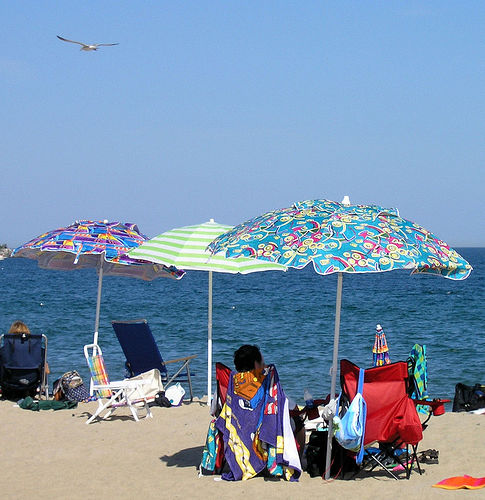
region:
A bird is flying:
[49, 27, 125, 62]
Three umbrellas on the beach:
[9, 190, 476, 478]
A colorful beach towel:
[197, 360, 306, 481]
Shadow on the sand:
[158, 441, 209, 471]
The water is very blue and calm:
[2, 245, 482, 411]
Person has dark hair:
[230, 340, 267, 375]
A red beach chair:
[335, 353, 427, 481]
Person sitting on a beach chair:
[3, 318, 52, 402]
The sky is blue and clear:
[1, 4, 483, 247]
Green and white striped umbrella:
[122, 214, 292, 280]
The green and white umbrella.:
[134, 218, 287, 276]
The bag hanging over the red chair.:
[336, 361, 363, 446]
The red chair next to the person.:
[338, 354, 419, 476]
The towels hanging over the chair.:
[221, 370, 293, 480]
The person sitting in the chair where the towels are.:
[233, 341, 307, 453]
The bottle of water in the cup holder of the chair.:
[301, 386, 313, 405]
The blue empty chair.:
[114, 320, 193, 397]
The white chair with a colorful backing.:
[84, 341, 149, 419]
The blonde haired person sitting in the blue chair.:
[9, 320, 48, 396]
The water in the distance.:
[6, 255, 484, 388]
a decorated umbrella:
[204, 181, 473, 293]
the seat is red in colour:
[321, 345, 419, 453]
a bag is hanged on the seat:
[316, 314, 372, 470]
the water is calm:
[237, 285, 286, 337]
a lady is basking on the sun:
[4, 285, 75, 404]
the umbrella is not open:
[368, 303, 406, 386]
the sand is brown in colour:
[12, 438, 156, 487]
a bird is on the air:
[41, 31, 119, 68]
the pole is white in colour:
[323, 264, 338, 496]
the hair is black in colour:
[223, 343, 267, 372]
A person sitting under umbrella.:
[203, 338, 419, 469]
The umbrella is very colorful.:
[250, 199, 446, 272]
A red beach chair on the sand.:
[337, 358, 425, 466]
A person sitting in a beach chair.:
[217, 331, 307, 466]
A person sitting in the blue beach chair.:
[3, 318, 60, 403]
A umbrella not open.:
[364, 313, 404, 377]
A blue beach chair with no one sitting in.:
[116, 313, 192, 401]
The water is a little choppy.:
[102, 274, 413, 343]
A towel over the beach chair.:
[208, 384, 302, 469]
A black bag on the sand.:
[445, 365, 481, 411]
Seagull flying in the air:
[52, 33, 124, 58]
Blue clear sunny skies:
[0, 6, 483, 198]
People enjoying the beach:
[0, 207, 479, 490]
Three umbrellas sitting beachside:
[23, 203, 477, 482]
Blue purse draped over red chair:
[330, 357, 436, 476]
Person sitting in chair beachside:
[208, 340, 307, 479]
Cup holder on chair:
[430, 394, 447, 416]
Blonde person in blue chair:
[0, 316, 52, 395]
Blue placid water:
[7, 257, 483, 399]